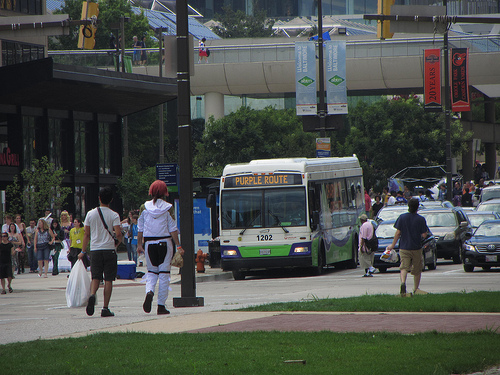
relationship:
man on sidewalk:
[387, 199, 434, 301] [241, 294, 491, 338]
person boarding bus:
[353, 202, 389, 275] [218, 165, 376, 269]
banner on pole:
[292, 48, 318, 112] [308, 14, 334, 135]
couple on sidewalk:
[88, 178, 201, 319] [241, 294, 491, 338]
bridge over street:
[145, 42, 487, 95] [189, 265, 345, 293]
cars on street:
[361, 195, 496, 271] [189, 265, 345, 293]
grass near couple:
[199, 341, 346, 366] [88, 178, 201, 319]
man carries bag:
[74, 196, 126, 316] [60, 259, 101, 303]